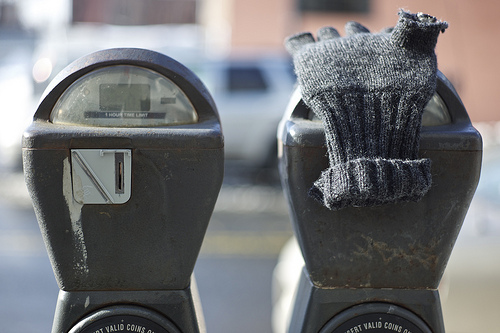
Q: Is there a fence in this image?
A: No, there are no fences.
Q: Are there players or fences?
A: No, there are no fences or players.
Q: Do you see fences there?
A: No, there are no fences.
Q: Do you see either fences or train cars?
A: No, there are no fences or train cars.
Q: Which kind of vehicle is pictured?
A: The vehicle is a car.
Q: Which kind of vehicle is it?
A: The vehicle is a car.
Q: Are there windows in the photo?
A: Yes, there is a window.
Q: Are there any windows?
A: Yes, there is a window.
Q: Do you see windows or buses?
A: Yes, there is a window.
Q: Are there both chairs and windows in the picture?
A: No, there is a window but no chairs.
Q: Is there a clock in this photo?
A: No, there are no clocks.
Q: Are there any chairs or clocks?
A: No, there are no clocks or chairs.